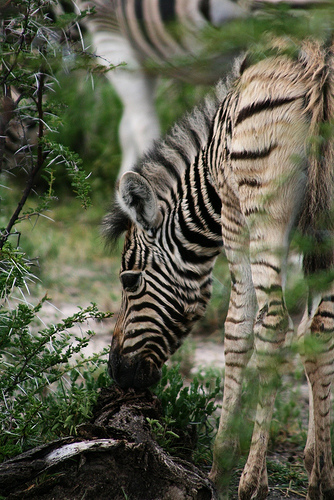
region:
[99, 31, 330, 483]
A baby zebra eating grass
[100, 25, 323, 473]
A baby zebra eating grass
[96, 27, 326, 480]
A baby zebra eating grass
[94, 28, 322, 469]
A baby zebra eating grass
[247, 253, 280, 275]
black stripe on zebra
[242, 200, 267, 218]
black stripe on zebra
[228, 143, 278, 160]
black stripe on zebra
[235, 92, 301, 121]
black stripe on zebra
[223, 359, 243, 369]
black stripe on zebra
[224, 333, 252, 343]
black stripe on zebra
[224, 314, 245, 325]
black stripe on zebra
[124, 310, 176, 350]
black stripe on zebra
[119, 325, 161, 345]
black stripe on zebra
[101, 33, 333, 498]
Young zebra in a forest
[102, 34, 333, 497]
Zebra with black and brown stripes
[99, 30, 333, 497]
Young zebra looking down at the ground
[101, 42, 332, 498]
Young zebra smelling something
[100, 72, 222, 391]
Head and neck of a small zebra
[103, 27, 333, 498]
Zebra with multi-colored stripes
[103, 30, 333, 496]
Small zebra in the woods sniffing something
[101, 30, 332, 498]
Small skinny zebra with his head down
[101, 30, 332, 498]
Baby zebra standing beside some plants